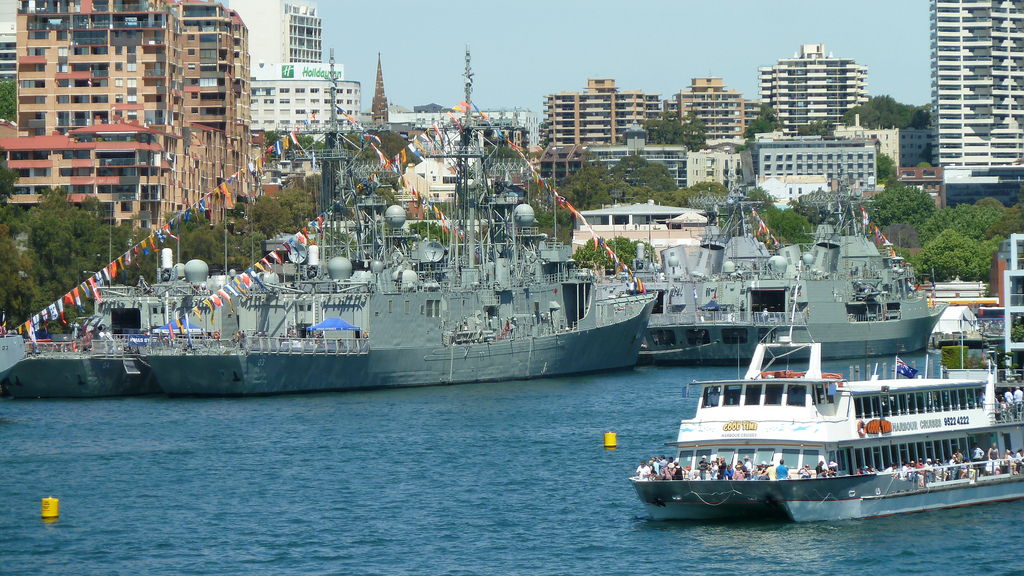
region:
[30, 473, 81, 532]
yellow buoy in the water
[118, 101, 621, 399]
large ships docked in the water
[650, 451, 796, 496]
people on the front deck of a boat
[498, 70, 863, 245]
buildings behind the docked ships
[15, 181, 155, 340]
trees growing near the docks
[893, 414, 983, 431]
writing on the side of the boat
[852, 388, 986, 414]
top row of windows on the white boat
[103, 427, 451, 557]
water is clear and calm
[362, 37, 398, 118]
spire on top of a building in the distance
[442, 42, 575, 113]
a view of sky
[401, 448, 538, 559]
a view of water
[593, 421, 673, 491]
a view of mark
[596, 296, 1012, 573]
a view of steamer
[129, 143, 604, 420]
a view of steamer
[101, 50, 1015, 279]
a view of building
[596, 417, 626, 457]
yellow buoy in the water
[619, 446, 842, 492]
people on the front deck of the boat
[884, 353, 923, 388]
blue flag on the boat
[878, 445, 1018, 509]
people on the side deck of the white boat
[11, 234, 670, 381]
large grey boats docked next to each other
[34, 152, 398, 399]
strings of flags going down toward the water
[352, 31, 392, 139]
large spire on top of a building in the distance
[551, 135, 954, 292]
trees dotting the land beyond the docks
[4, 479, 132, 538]
a yellow buoy in the water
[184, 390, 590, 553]
the water is blue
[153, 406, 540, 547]
the water is calm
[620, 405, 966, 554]
people are on the boat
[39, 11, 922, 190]
buildings are in the background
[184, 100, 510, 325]
multi colored flags on the boat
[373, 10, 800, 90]
the sky is partly cloudy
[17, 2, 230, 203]
a building that is brown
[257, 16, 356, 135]
a building that is white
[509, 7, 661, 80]
a sky that is blue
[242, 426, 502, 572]
water that is blue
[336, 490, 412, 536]
ripples inside of the lake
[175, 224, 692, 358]
a boat that is grey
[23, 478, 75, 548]
a buoy that is orange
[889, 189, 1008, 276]
a tree that is green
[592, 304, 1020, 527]
large ship in the blue waters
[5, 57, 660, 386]
large ship in the blue waters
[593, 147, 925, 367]
large ship in the blue waters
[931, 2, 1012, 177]
large building in the background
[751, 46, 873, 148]
large building in the background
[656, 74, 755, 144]
large building in the background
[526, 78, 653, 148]
large building in the background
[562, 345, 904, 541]
front of the boat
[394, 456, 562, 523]
water next to boat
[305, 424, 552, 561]
waves in the water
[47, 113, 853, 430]
gray ships near the boat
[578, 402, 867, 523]
people on the boat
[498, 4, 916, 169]
buildings in the distance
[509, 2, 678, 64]
sky above the land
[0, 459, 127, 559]
yellow object in water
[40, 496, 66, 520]
The plastic yellow item in the water.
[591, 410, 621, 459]
The yellow device in the water.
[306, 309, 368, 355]
The bluw umbrella tent.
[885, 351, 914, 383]
The blue flag on the boat.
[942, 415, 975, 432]
The blue letter on the boat.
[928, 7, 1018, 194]
The white building on the right.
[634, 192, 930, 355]
The large ship on the right.